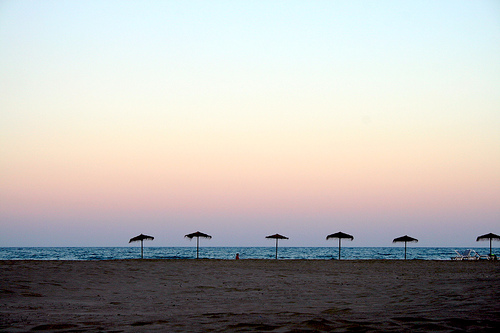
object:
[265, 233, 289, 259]
parasol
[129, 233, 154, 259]
parasol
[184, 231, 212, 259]
parasol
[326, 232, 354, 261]
parasol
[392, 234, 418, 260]
parasol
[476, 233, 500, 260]
parasol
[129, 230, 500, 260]
parasols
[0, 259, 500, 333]
beach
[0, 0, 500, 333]
background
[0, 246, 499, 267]
plate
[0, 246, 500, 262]
ocean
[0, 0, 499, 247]
sky